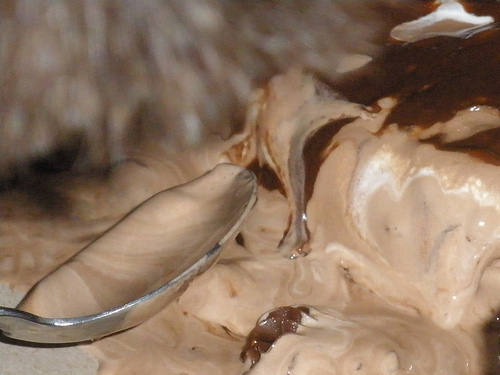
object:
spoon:
[0, 162, 268, 346]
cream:
[0, 62, 500, 375]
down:
[232, 69, 371, 261]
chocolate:
[329, 35, 496, 168]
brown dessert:
[0, 51, 500, 374]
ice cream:
[277, 37, 499, 372]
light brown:
[378, 178, 499, 300]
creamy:
[260, 163, 434, 331]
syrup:
[289, 21, 499, 251]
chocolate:
[208, 110, 359, 255]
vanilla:
[54, 237, 484, 371]